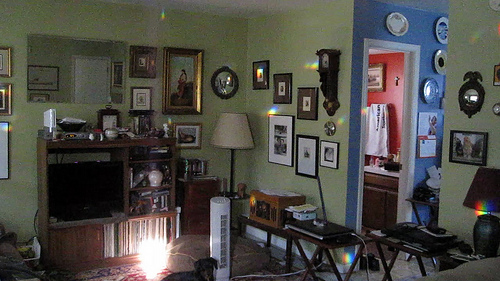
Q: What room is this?
A: Living room.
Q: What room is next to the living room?
A: Bathroom.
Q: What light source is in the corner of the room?
A: Lamp.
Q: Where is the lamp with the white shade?
A: Corner.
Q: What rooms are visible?
A: Living room and bathroom.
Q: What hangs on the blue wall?
A: Plates.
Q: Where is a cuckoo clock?
A: Green wall.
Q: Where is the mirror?
A: Over the tv stand.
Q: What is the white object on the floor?
A: Air filter.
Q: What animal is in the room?
A: Dog.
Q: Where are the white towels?
A: Bathroom rack.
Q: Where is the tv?
A: Entertainment center.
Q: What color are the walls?
A: Green.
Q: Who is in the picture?
A: Nobody.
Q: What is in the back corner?
A: A lamp.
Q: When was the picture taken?
A: Daytime.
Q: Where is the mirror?
A: On the wall.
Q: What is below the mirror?
A: A television.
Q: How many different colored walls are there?
A: Three.